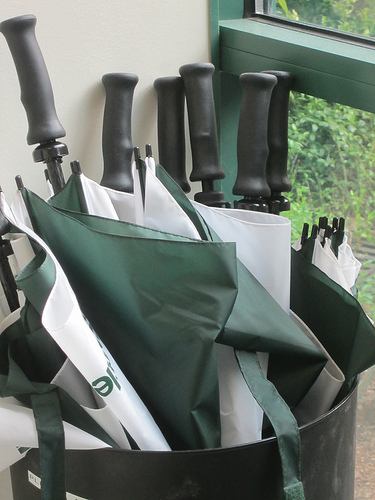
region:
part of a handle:
[196, 122, 224, 158]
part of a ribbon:
[272, 418, 303, 451]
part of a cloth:
[188, 367, 214, 426]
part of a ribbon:
[275, 436, 302, 482]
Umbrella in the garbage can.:
[40, 181, 295, 482]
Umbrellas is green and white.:
[54, 209, 290, 429]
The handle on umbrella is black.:
[87, 60, 238, 170]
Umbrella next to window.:
[216, 12, 374, 233]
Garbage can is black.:
[27, 408, 347, 498]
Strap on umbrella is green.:
[237, 365, 318, 487]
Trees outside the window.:
[292, 106, 366, 209]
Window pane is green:
[221, 18, 365, 107]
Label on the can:
[19, 469, 65, 497]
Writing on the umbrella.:
[79, 349, 117, 404]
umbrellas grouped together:
[0, 13, 373, 499]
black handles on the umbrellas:
[0, 13, 293, 196]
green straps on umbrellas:
[30, 345, 305, 499]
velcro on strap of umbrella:
[282, 481, 303, 498]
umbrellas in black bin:
[9, 371, 360, 498]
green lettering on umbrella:
[82, 314, 121, 395]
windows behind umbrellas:
[253, 0, 374, 499]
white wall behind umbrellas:
[0, 0, 211, 499]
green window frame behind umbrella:
[206, 0, 373, 209]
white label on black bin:
[27, 469, 85, 499]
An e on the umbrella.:
[85, 364, 115, 402]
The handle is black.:
[2, 12, 68, 156]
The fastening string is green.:
[239, 353, 312, 498]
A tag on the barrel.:
[23, 466, 111, 498]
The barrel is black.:
[20, 386, 373, 497]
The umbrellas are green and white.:
[0, 183, 294, 432]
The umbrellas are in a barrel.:
[4, 18, 359, 494]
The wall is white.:
[37, 6, 202, 66]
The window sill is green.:
[211, 8, 373, 101]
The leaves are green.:
[291, 99, 374, 207]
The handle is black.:
[3, 18, 73, 161]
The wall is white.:
[46, 3, 198, 68]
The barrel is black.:
[7, 385, 362, 499]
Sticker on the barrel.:
[17, 465, 89, 498]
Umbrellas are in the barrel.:
[5, 23, 355, 496]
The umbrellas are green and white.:
[3, 176, 352, 437]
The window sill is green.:
[217, 14, 374, 107]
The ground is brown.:
[354, 392, 373, 498]